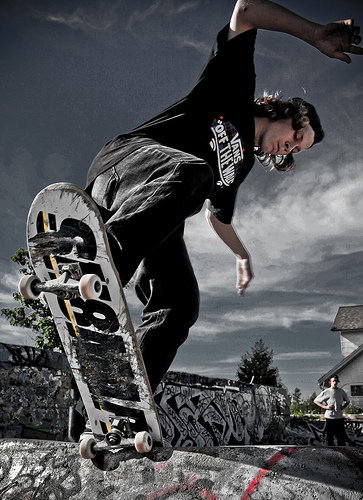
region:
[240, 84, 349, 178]
a person with long hair.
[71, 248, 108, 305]
a wheel on a skateboard.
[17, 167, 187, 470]
a skateboard with four wheels.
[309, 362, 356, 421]
a man in a gray shirt.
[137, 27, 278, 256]
a black vans t shirt.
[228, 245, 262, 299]
a left human hand.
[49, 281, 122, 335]
a letter written on the bottom of a skateboard.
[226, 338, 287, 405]
a tree with lots of green needles.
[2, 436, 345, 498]
the side of a ramp.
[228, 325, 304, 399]
a lush green pine tree.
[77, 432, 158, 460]
two skateboard wheels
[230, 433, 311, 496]
red line on the grown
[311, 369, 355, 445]
man with gray shirt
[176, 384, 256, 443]
lots of graffiti on the wall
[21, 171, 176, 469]
black letters on bottom of skateboard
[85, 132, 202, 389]
man with black jeans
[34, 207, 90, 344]
yellow and black line on skateboard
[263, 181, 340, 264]
gray and cloudy sky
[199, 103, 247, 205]
white letters on a black T-shirt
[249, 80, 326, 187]
guy with long hair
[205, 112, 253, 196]
logo on boy's shirt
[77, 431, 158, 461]
rear wheels on skateboard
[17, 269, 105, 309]
front wheels on skateboard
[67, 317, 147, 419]
scuffs on bottom of skateboard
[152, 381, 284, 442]
graffiti on retaining wall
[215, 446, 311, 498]
red paint on concrete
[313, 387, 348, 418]
gray shirt on boy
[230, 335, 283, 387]
top of pine tree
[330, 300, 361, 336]
roof of two story home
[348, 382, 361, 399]
window of house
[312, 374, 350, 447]
Man standing with his hands on his hips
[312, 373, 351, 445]
Man wearing a white shirt and black pants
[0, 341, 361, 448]
Black and white graffiti on a concrete wall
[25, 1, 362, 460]
Young man riding a skateboard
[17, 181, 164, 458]
Used white and black skateboard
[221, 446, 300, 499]
Red spray paint on concrete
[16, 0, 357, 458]
Skateboarder wearing a Vans t-shirt and black jeans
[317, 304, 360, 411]
White two story house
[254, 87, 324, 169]
Head of curly hair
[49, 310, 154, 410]
Large amount of scraping on a skateboard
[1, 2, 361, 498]
guy on skateboard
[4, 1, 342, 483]
guy wearing a black hat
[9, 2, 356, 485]
guy wearing black jeans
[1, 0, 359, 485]
guy leaning on skateboard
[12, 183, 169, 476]
skateboard with scratches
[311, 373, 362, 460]
guy with hands on his hips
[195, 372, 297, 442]
graffiti on the wall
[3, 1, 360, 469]
guy about to fall off ramp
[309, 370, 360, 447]
guy standing up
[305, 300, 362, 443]
guy standing near house